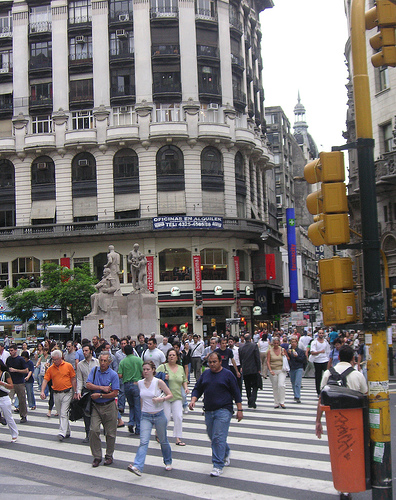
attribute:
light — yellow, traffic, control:
[301, 140, 368, 244]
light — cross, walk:
[302, 140, 360, 322]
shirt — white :
[133, 376, 164, 411]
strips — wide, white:
[254, 402, 302, 485]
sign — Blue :
[152, 214, 224, 230]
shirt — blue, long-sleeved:
[190, 366, 240, 415]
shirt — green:
[153, 360, 191, 402]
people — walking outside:
[2, 316, 374, 478]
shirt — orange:
[42, 360, 74, 391]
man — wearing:
[29, 342, 83, 443]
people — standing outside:
[0, 318, 333, 470]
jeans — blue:
[204, 407, 230, 463]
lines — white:
[238, 427, 310, 493]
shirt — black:
[213, 347, 235, 362]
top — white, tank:
[136, 373, 172, 415]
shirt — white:
[312, 351, 368, 412]